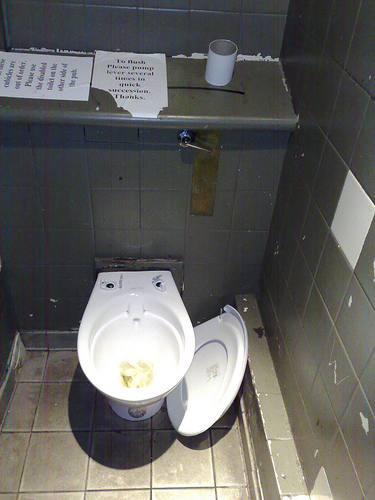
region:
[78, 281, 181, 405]
this is the toilet sink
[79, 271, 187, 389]
the toilet sink is white in color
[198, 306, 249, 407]
this is the lid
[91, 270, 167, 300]
the lid is broken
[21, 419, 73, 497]
this is the floor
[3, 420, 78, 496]
the floor is tiled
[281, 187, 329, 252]
this is the wall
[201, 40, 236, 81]
this is a tin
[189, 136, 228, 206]
this is a metal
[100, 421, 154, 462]
this is the shadow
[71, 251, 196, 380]
white bowl of toilet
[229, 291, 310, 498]
grey ledge near wall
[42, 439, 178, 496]
grey tile on floor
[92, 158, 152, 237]
dark grey tile on wall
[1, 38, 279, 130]
grey ledge on wall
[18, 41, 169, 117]
white papers on ledge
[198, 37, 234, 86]
white cup on ledge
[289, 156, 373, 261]
white tile on wall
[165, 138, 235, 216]
brown board on ledge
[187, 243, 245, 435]
white toilet seat on floor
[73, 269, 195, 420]
a white porcelain toilet basin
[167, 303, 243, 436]
a plastic white toilet seat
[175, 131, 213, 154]
a toilet flush valve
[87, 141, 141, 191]
a grey wall tile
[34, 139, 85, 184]
a grey wall tile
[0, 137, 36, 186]
a grey wall tile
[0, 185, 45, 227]
a grey wall tile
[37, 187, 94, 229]
a grey wall tile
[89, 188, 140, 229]
a grey wall tile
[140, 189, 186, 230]
a grey wall tile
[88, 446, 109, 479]
edge of a shade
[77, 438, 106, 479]
aprt of a line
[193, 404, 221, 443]
edge of a lid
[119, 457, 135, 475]
part of a floor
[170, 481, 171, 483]
edge of a toilet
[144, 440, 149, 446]
edge of a shadow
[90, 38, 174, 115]
what paper on the shelf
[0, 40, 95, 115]
white paper on the shelf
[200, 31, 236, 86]
roll of tissue on the shelf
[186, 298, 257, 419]
toilet bowl lid on the floor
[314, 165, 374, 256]
white tile on the wall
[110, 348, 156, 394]
tissue in the toilet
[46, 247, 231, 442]
toilet bowl attached to wall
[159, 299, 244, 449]
toilet seat lid on the floor